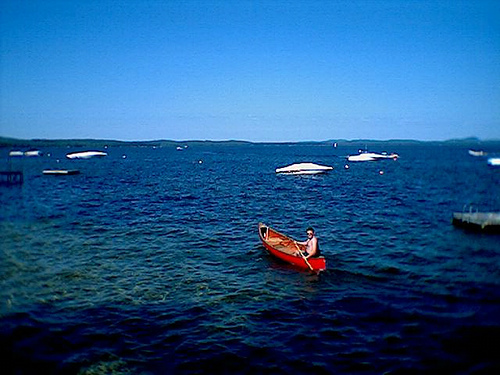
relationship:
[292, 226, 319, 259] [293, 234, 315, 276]
man holding paddle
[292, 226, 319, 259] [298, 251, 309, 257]
man in bathing suit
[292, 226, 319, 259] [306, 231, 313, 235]
man wearing sunglasses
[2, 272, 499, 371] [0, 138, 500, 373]
shadow in water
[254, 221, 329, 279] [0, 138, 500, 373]
boat in water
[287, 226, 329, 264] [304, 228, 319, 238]
man wearing sunglasses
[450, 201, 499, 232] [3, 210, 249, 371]
dock visible in water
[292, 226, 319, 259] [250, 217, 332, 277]
man sitting in boat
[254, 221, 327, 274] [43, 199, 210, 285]
boat floating on water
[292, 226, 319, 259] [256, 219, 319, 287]
man inside boat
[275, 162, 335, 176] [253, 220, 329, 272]
boat behind red boat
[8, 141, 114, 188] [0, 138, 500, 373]
boats floating on water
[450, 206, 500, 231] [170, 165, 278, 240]
dock near water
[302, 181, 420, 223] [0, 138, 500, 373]
waves visible on water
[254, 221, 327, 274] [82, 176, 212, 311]
boat in water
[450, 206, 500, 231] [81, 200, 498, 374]
dock in water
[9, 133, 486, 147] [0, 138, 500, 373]
land behind water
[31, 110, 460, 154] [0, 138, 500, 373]
blue sky over water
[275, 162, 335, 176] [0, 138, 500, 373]
boat on water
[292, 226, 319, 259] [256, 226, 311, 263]
man in boat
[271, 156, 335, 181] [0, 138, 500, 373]
boat on water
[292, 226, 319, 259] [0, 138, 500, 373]
man in a boat on water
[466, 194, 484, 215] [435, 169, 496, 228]
silver handles to a ladder on a dock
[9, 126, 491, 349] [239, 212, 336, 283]
water with boats